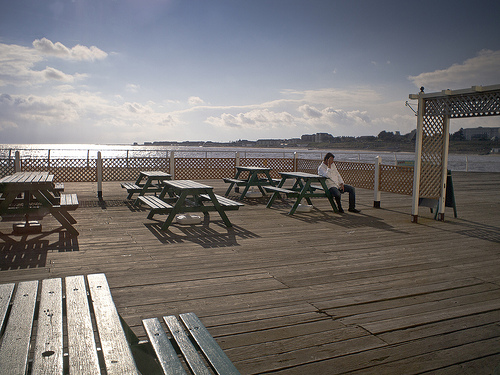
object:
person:
[311, 151, 368, 221]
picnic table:
[258, 168, 348, 218]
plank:
[307, 272, 483, 309]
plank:
[318, 282, 496, 320]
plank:
[356, 299, 500, 335]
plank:
[373, 310, 500, 348]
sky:
[0, 2, 500, 84]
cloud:
[0, 32, 111, 68]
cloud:
[196, 85, 361, 131]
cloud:
[296, 96, 387, 132]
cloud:
[400, 46, 498, 87]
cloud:
[155, 111, 179, 130]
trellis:
[405, 78, 500, 224]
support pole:
[410, 99, 426, 223]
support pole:
[437, 101, 451, 223]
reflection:
[23, 142, 147, 158]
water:
[0, 144, 500, 171]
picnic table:
[219, 160, 283, 205]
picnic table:
[134, 176, 247, 238]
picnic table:
[0, 169, 81, 238]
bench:
[313, 173, 352, 214]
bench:
[262, 171, 309, 217]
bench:
[220, 163, 262, 202]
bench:
[201, 182, 245, 231]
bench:
[133, 178, 185, 232]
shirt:
[315, 162, 351, 191]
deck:
[1, 167, 62, 189]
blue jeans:
[329, 183, 361, 214]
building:
[459, 126, 500, 144]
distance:
[1, 114, 500, 160]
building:
[256, 137, 289, 147]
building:
[298, 131, 334, 146]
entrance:
[447, 117, 500, 228]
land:
[134, 141, 500, 176]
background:
[1, 25, 499, 172]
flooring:
[6, 180, 498, 374]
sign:
[424, 167, 459, 220]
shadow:
[333, 208, 413, 237]